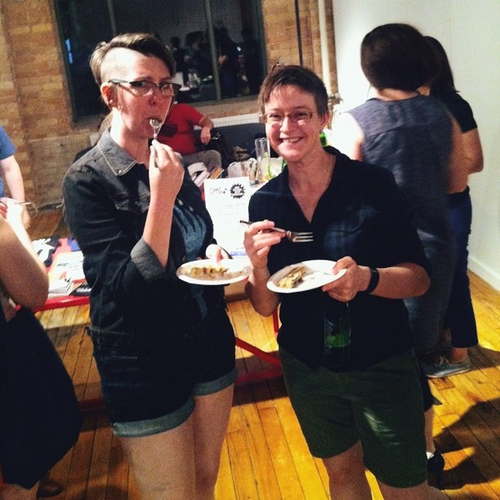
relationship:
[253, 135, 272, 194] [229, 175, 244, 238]
glass receptacle on table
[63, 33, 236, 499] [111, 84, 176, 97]
woman wearing glasses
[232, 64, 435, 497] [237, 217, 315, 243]
woman holding fork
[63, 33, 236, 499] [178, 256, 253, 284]
woman holding plate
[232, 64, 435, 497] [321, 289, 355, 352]
woman holding beer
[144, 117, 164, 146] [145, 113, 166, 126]
fork in lady's mouth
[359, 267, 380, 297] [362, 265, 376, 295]
wristwatch on lady's wrist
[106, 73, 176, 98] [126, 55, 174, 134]
glasses on lady's face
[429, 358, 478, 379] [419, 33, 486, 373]
shoes on lady's foot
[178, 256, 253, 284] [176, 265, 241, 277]
plate of food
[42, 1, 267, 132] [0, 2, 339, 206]
window in wall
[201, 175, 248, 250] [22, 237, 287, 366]
paper sign on table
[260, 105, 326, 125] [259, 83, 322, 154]
glasses on woman's face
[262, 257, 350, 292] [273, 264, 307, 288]
plate with food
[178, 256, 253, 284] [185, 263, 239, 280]
plate with food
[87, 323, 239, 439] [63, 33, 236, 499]
shorts on woman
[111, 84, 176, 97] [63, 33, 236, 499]
glasses on woman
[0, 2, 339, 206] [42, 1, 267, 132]
wall with window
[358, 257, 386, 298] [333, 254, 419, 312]
wristband on arm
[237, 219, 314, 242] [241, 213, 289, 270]
fork in hand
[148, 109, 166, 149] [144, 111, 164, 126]
utensil in mouth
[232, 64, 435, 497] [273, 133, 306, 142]
woman wearing smiling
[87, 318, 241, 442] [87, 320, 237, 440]
shorts are short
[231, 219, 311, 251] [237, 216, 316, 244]
fork wearing metal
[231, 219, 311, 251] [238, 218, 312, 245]
fork wearing silver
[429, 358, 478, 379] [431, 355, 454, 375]
shoes wearing blue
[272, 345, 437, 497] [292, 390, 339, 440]
shorts are green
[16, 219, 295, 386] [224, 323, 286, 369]
table has leg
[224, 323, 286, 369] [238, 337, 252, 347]
leg wearing red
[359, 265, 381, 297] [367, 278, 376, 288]
wristwatch wearing black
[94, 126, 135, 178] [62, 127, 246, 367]
collar on shirt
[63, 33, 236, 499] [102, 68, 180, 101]
woman has glasses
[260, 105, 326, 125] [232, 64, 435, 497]
glasses on woman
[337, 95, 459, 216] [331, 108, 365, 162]
shirt wearing sleeveless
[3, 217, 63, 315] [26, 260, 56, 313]
elbow wearing bent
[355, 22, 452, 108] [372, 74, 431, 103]
hair wearing short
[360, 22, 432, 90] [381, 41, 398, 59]
hair wearing brown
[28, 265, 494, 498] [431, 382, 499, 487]
floor has shadow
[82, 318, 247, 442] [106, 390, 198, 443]
shorts have cuff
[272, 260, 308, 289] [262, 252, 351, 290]
food on plate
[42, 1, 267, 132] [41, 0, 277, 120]
window wearing big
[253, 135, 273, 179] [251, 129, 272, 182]
glass wearing tall